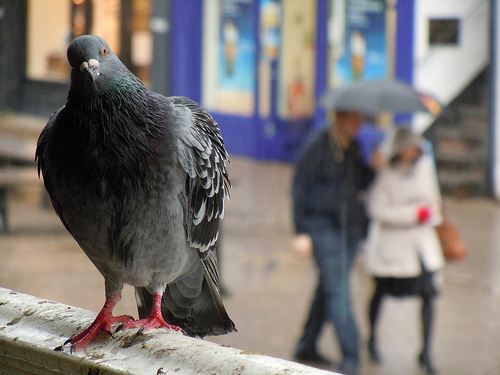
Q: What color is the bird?
A: Gray.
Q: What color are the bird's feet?
A: Pink.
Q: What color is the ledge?
A: Gray.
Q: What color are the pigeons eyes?
A: Red.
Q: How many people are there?
A: 2.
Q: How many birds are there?
A: One.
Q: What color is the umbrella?
A: Black.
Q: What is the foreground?
A: A pigeon.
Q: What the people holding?
A: An umbrella.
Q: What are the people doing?
A: Walking.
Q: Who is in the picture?
A: A man and a woman.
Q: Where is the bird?
A: Perched on a ledge.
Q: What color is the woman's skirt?
A: Black.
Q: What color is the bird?
A: Red and gray.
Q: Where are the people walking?
A: On a sidewalk.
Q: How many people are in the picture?
A: 2.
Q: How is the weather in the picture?
A: Rainy.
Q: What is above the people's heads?
A: An umbrella.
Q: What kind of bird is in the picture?
A: A pigeon.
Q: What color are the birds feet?
A: Red.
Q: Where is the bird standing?
A: On a ledge.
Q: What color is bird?
A: Gray.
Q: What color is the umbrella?
A: Black.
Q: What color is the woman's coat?
A: White.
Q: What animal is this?
A: A bird.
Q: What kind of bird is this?
A: Pigeon.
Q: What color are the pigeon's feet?
A: Red.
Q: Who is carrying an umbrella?
A: The man in the back.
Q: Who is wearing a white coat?
A: The woman in the back.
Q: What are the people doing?
A: Walking in the rain.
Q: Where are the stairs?
A: Across the walkway.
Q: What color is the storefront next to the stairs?
A: Blue.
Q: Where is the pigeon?
A: Standing on a ledge.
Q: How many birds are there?
A: 1.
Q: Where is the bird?
A: On the left.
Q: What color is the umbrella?
A: Gray.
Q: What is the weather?
A: Rainy.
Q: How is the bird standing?
A: On both feet.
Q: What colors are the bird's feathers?
A: Black, gray, green, and purple.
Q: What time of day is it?
A: Day time.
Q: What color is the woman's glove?
A: Red.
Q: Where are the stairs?
A: On the right behind the people.